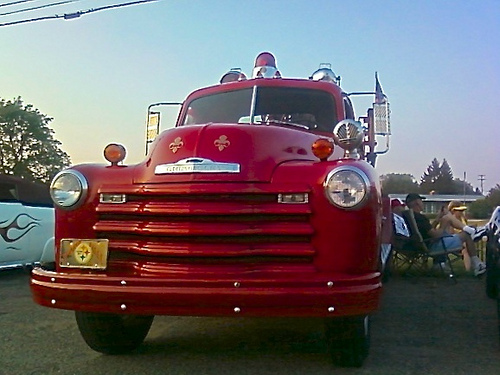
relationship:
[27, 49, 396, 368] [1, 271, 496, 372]
truck on pavement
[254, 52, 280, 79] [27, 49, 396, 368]
siren light on truck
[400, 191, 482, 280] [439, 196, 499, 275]
man next to woman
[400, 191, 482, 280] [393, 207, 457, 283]
man sitting on chair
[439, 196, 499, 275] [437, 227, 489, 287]
woman sitting on chair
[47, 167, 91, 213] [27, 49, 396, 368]
headlight on truck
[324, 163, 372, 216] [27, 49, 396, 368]
headlight on truck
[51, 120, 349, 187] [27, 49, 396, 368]
hood on truck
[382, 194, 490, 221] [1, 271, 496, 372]
house behind street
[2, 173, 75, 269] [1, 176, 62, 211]
car has top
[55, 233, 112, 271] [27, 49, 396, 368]
tag on truck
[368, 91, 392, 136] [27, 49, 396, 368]
mirror on truck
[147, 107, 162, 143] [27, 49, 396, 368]
mirror on truck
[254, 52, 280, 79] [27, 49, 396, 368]
light on truck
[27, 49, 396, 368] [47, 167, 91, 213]
truck has headlight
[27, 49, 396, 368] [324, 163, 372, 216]
truck has headlight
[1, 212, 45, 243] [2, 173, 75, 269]
flame design on car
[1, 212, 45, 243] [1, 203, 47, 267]
flame design on car door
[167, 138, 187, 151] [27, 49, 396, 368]
fleurs-de-lis on truck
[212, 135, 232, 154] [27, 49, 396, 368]
fleurs-de-lis on truck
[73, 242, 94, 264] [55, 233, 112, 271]
pittsburgh steelers on license plate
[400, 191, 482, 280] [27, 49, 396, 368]
man next to truck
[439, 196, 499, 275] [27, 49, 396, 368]
woman next to truck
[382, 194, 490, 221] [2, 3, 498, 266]
building in background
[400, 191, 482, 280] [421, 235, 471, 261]
man in shorts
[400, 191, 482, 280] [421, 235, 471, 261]
man wearing shorts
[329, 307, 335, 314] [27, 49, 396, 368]
stud on truck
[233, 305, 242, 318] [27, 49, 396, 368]
stud on truck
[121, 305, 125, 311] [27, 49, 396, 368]
stud on truck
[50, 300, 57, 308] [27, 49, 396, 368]
stud on truck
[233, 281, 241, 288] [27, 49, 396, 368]
stud on truck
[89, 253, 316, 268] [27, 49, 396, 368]
grove on truck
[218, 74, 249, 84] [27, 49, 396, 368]
light on truck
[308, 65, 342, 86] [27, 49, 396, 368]
light on truck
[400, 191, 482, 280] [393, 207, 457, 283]
man in chair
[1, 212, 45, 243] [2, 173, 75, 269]
design on white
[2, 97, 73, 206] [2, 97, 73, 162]
tree has top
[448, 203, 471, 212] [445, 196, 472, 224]
visor on woman's head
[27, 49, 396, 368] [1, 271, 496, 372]
truck on ground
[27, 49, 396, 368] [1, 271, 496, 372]
truck on grass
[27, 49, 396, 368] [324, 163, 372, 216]
truck has light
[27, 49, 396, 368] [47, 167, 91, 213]
truck has light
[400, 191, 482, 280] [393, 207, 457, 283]
man on chair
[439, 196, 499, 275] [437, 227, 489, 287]
woman on chair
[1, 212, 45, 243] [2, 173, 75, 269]
design on vehicle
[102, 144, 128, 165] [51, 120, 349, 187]
light on hood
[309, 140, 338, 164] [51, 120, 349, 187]
light on hood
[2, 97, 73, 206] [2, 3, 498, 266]
tree in background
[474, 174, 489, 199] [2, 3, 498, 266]
electrical pole in background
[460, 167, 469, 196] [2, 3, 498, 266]
electrical pole in background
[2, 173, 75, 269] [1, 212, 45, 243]
car has flames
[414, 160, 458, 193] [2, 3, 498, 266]
trees in background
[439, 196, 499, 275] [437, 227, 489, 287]
woman in chair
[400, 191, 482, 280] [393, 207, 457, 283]
man in lawn chair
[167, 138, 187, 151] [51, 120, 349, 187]
emblem on hood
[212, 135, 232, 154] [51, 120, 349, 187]
emblem on hood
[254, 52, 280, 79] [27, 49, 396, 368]
siren on truck